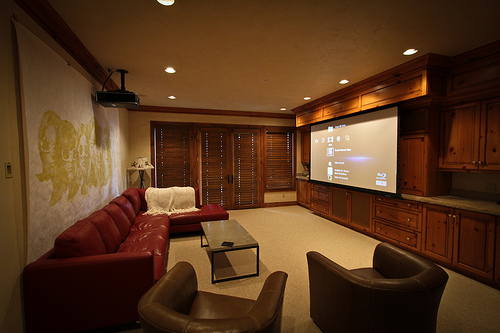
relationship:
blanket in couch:
[141, 186, 203, 216] [22, 180, 244, 324]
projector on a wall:
[95, 70, 140, 108] [0, 0, 130, 331]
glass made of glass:
[200, 219, 256, 249] [198, 207, 260, 256]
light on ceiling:
[160, 61, 180, 81] [135, 1, 320, 98]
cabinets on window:
[153, 120, 292, 206] [161, 132, 268, 202]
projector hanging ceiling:
[95, 67, 139, 109] [91, 21, 234, 83]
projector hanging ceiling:
[95, 67, 139, 109] [19, 0, 493, 110]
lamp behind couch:
[123, 154, 152, 188] [23, 182, 223, 331]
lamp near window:
[125, 153, 150, 178] [150, 125, 190, 177]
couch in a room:
[23, 182, 223, 331] [5, 0, 499, 330]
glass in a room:
[200, 219, 256, 249] [5, 0, 499, 330]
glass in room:
[200, 219, 256, 249] [54, 38, 497, 331]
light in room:
[149, 52, 199, 129] [5, 0, 499, 330]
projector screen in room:
[308, 105, 398, 197] [5, 0, 499, 330]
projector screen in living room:
[305, 103, 402, 197] [0, 0, 497, 329]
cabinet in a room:
[402, 131, 449, 203] [18, 92, 477, 331]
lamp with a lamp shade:
[127, 157, 154, 189] [124, 155, 154, 170]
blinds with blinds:
[265, 127, 293, 187] [154, 127, 291, 204]